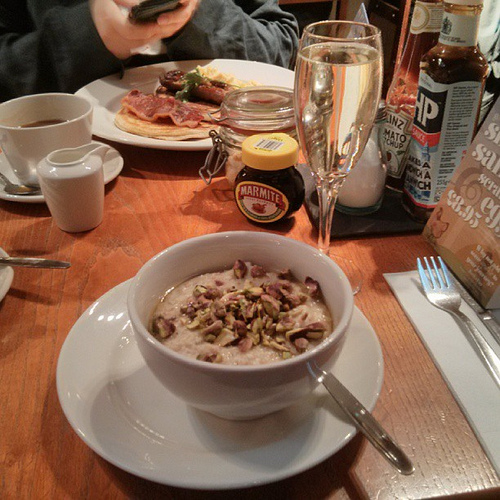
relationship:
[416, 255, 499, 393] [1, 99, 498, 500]
fork on table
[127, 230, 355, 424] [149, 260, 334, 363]
bowl of soup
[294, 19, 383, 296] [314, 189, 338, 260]
wine glass with stem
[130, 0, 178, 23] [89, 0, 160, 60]
cellphone in hand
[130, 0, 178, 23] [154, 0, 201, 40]
cellphone in hand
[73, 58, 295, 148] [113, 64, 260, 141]
plate of food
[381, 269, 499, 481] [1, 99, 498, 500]
napkin on table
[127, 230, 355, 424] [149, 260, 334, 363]
bowl of cereal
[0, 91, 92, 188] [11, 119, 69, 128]
cup of coffee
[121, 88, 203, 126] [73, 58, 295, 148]
bacon on plate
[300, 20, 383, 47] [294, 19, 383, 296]
top of wine glass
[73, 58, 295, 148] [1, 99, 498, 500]
plate on table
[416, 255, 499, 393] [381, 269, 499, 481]
fork on napkin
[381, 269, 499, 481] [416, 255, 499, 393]
napkin under fork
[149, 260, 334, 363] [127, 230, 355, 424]
food in bowl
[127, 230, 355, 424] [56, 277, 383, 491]
bowl on plate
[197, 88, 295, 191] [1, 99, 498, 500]
sugar holder on table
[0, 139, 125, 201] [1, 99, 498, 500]
saucer on table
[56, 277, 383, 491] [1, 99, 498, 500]
plate on table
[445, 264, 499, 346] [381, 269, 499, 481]
knife on napkin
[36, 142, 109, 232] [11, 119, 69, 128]
creamer dish for coffee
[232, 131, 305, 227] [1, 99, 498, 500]
marmite on table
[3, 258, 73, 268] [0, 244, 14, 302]
utensil handle on plate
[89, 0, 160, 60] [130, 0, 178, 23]
hand holding cellphone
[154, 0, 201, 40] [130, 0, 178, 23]
hand holding cellphone